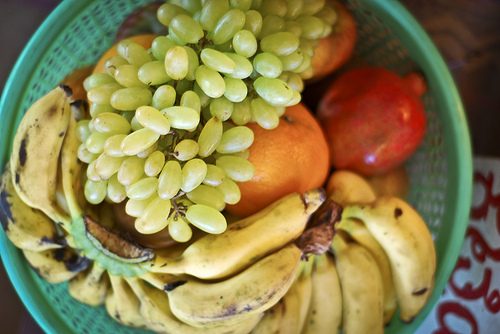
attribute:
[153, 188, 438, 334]
bananas — yellow, black, overripe, small, ripe, discolored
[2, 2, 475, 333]
bowl — full, green, plastic, circular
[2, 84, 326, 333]
bananas — yellow, black, overripe, small, ripe, discolored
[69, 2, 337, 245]
grapes — green, fresh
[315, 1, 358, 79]
orange — round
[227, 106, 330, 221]
orange — round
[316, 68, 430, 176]
pomegranate — red, bright red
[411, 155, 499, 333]
paper — white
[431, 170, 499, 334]
lettering — red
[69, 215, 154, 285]
banana stem — green